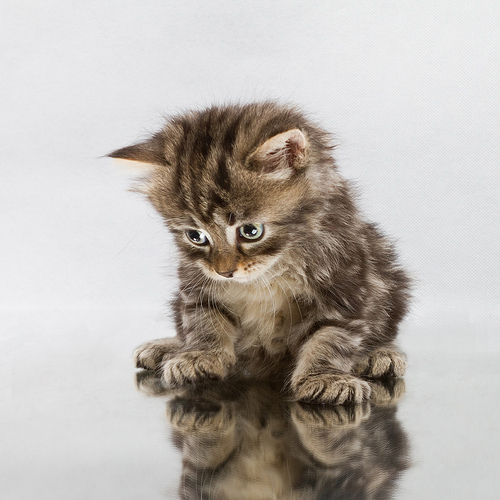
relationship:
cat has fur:
[99, 102, 415, 405] [160, 115, 410, 362]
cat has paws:
[99, 102, 415, 405] [115, 333, 374, 413]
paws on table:
[115, 333, 374, 413] [1, 344, 493, 494]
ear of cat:
[242, 126, 322, 168] [102, 103, 427, 495]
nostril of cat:
[227, 272, 234, 278] [99, 102, 415, 405]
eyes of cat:
[180, 217, 267, 248] [99, 102, 415, 405]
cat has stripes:
[99, 102, 415, 405] [166, 111, 249, 216]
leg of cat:
[133, 331, 190, 371] [99, 102, 415, 405]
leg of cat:
[353, 338, 406, 378] [99, 102, 415, 405]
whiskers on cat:
[175, 255, 315, 335] [139, 99, 432, 453]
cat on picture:
[130, 112, 415, 433] [8, 4, 495, 498]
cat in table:
[99, 102, 415, 405] [79, 393, 240, 484]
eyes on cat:
[171, 217, 274, 248] [82, 101, 422, 427]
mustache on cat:
[212, 272, 242, 284] [125, 155, 418, 400]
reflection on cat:
[148, 387, 420, 499] [99, 102, 415, 405]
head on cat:
[115, 86, 321, 328] [88, 75, 419, 438]